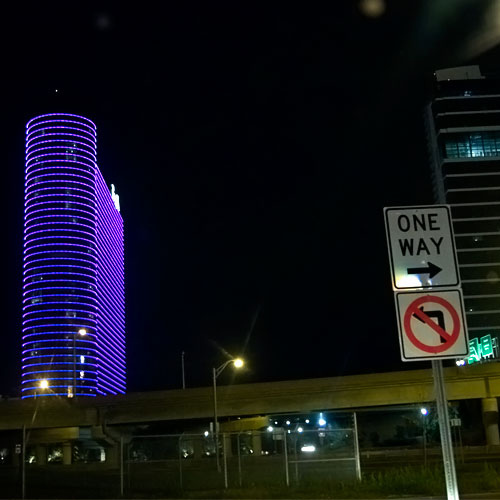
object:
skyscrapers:
[21, 112, 127, 398]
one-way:
[396, 211, 449, 257]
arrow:
[406, 260, 443, 279]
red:
[403, 295, 461, 355]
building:
[425, 63, 500, 362]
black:
[366, 40, 408, 87]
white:
[384, 204, 470, 362]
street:
[0, 477, 500, 498]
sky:
[33, 23, 488, 50]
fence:
[122, 427, 361, 488]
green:
[469, 333, 495, 362]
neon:
[21, 112, 128, 400]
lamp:
[227, 356, 251, 376]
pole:
[209, 364, 222, 474]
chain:
[123, 429, 358, 480]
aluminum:
[282, 432, 290, 488]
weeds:
[226, 466, 499, 497]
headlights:
[299, 443, 317, 453]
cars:
[183, 448, 223, 458]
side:
[94, 161, 128, 399]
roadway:
[0, 356, 500, 411]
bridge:
[0, 364, 499, 447]